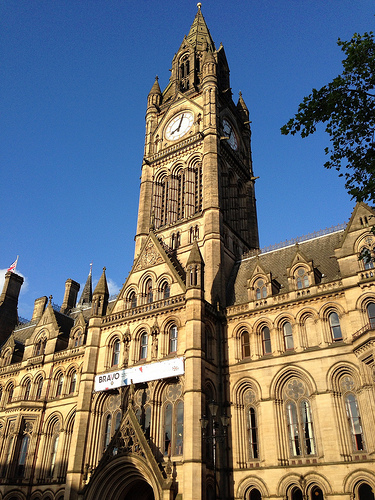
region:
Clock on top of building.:
[157, 106, 200, 142]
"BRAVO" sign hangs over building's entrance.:
[92, 354, 185, 391]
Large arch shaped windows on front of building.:
[234, 362, 373, 403]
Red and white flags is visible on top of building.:
[6, 250, 22, 275]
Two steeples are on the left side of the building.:
[81, 259, 118, 301]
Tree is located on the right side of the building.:
[276, 24, 373, 235]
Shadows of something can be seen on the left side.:
[3, 446, 79, 498]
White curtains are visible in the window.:
[267, 369, 333, 461]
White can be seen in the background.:
[69, 256, 125, 310]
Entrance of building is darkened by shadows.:
[86, 431, 177, 498]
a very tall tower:
[125, 6, 238, 255]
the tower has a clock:
[129, 77, 271, 217]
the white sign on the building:
[72, 339, 217, 401]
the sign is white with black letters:
[74, 346, 195, 405]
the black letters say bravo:
[86, 365, 132, 403]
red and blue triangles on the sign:
[121, 352, 256, 412]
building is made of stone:
[191, 327, 356, 456]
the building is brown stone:
[30, 317, 111, 437]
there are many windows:
[30, 356, 121, 413]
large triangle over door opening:
[84, 406, 169, 493]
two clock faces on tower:
[156, 102, 243, 149]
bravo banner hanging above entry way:
[87, 360, 187, 388]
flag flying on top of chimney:
[6, 256, 21, 278]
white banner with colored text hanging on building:
[88, 365, 180, 384]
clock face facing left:
[155, 108, 200, 137]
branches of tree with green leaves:
[278, 25, 373, 295]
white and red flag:
[6, 253, 29, 278]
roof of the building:
[1, 243, 350, 337]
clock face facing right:
[216, 114, 246, 154]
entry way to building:
[72, 423, 180, 494]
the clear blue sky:
[14, 17, 101, 113]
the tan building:
[1, 202, 371, 495]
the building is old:
[6, 219, 369, 498]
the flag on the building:
[3, 251, 27, 271]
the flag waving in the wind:
[5, 251, 24, 272]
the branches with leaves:
[267, 32, 373, 231]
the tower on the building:
[122, 3, 267, 254]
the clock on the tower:
[154, 105, 203, 140]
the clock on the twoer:
[215, 106, 249, 158]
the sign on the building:
[74, 345, 214, 392]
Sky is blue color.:
[22, 81, 87, 210]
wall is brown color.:
[35, 324, 346, 477]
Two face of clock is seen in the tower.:
[156, 104, 260, 166]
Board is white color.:
[69, 359, 204, 400]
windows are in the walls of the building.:
[1, 326, 336, 457]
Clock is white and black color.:
[155, 103, 206, 147]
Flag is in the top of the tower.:
[5, 254, 32, 291]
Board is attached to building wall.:
[79, 345, 197, 403]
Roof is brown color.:
[245, 239, 342, 288]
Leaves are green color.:
[302, 54, 374, 180]